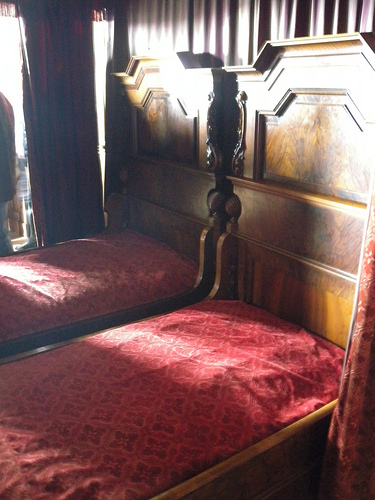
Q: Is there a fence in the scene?
A: No, there are no fences.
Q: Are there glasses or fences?
A: No, there are no fences or glasses.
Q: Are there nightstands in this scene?
A: No, there are no nightstands.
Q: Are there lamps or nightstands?
A: No, there are no nightstands or lamps.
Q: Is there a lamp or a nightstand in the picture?
A: No, there are no nightstands or lamps.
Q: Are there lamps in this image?
A: No, there are no lamps.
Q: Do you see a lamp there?
A: No, there are no lamps.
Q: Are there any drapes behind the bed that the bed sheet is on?
A: Yes, there are drapes behind the bed.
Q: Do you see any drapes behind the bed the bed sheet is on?
A: Yes, there are drapes behind the bed.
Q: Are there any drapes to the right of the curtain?
A: Yes, there are drapes to the right of the curtain.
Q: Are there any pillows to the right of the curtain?
A: No, there are drapes to the right of the curtain.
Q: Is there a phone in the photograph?
A: No, there are no phones.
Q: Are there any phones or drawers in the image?
A: No, there are no phones or drawers.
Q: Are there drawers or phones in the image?
A: No, there are no phones or drawers.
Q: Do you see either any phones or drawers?
A: No, there are no phones or drawers.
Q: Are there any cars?
A: No, there are no cars.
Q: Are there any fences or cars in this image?
A: No, there are no cars or fences.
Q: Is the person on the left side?
A: Yes, the person is on the left of the image.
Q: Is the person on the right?
A: No, the person is on the left of the image.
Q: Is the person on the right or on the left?
A: The person is on the left of the image.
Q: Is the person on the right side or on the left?
A: The person is on the left of the image.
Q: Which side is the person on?
A: The person is on the left of the image.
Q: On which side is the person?
A: The person is on the left of the image.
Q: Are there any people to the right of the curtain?
A: No, the person is to the left of the curtain.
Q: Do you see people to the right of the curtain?
A: No, the person is to the left of the curtain.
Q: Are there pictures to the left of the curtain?
A: No, there is a person to the left of the curtain.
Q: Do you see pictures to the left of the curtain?
A: No, there is a person to the left of the curtain.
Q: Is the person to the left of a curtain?
A: Yes, the person is to the left of a curtain.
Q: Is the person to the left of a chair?
A: No, the person is to the left of a curtain.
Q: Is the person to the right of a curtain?
A: No, the person is to the left of a curtain.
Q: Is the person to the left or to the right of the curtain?
A: The person is to the left of the curtain.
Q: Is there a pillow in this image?
A: No, there are no pillows.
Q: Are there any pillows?
A: No, there are no pillows.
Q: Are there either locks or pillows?
A: No, there are no pillows or locks.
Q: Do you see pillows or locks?
A: No, there are no pillows or locks.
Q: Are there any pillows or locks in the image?
A: No, there are no pillows or locks.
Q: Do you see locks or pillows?
A: No, there are no pillows or locks.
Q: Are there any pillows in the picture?
A: No, there are no pillows.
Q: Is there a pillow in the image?
A: No, there are no pillows.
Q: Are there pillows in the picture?
A: No, there are no pillows.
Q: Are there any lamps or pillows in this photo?
A: No, there are no pillows or lamps.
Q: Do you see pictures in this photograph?
A: No, there are no pictures.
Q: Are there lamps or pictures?
A: No, there are no pictures or lamps.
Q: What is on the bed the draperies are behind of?
A: The sheet is on the bed.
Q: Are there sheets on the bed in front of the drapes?
A: Yes, there is a sheet on the bed.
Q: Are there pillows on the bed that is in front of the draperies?
A: No, there is a sheet on the bed.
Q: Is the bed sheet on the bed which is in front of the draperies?
A: Yes, the sheet is on the bed.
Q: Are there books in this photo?
A: No, there are no books.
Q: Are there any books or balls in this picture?
A: No, there are no books or balls.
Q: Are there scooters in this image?
A: No, there are no scooters.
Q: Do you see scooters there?
A: No, there are no scooters.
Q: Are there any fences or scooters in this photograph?
A: No, there are no scooters or fences.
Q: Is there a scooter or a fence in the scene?
A: No, there are no scooters or fences.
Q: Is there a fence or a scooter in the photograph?
A: No, there are no scooters or fences.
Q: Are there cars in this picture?
A: No, there are no cars.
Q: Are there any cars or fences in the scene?
A: No, there are no cars or fences.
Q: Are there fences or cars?
A: No, there are no cars or fences.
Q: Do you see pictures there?
A: No, there are no pictures.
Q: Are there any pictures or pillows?
A: No, there are no pictures or pillows.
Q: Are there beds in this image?
A: Yes, there is a bed.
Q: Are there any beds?
A: Yes, there is a bed.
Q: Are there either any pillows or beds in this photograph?
A: Yes, there is a bed.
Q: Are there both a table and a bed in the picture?
A: No, there is a bed but no tables.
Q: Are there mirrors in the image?
A: No, there are no mirrors.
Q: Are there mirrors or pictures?
A: No, there are no mirrors or pictures.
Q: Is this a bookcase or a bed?
A: This is a bed.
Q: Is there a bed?
A: Yes, there is a bed.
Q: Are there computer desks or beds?
A: Yes, there is a bed.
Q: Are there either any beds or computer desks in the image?
A: Yes, there is a bed.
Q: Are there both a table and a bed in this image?
A: No, there is a bed but no tables.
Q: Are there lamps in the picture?
A: No, there are no lamps.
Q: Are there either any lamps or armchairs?
A: No, there are no lamps or armchairs.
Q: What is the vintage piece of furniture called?
A: The piece of furniture is a bed.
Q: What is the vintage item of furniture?
A: The piece of furniture is a bed.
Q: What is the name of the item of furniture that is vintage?
A: The piece of furniture is a bed.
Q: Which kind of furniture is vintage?
A: The furniture is a bed.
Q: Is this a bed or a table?
A: This is a bed.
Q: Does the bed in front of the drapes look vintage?
A: Yes, the bed is vintage.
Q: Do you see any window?
A: Yes, there is a window.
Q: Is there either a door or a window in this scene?
A: Yes, there is a window.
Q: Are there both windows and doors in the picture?
A: No, there is a window but no doors.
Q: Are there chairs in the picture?
A: No, there are no chairs.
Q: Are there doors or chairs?
A: No, there are no chairs or doors.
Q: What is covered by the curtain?
A: The window is covered by the curtain.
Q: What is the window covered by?
A: The window is covered by the curtain.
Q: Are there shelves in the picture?
A: No, there are no shelves.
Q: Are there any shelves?
A: No, there are no shelves.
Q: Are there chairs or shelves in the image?
A: No, there are no shelves or chairs.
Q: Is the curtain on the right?
A: No, the curtain is on the left of the image.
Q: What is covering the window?
A: The curtain is covering the window.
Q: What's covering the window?
A: The curtain is covering the window.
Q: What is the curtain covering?
A: The curtain is covering the window.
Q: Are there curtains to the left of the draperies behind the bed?
A: Yes, there is a curtain to the left of the draperies.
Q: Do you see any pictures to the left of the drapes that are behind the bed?
A: No, there is a curtain to the left of the drapes.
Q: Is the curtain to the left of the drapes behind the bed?
A: Yes, the curtain is to the left of the draperies.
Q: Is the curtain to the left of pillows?
A: No, the curtain is to the left of the draperies.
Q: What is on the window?
A: The curtain is on the window.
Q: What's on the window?
A: The curtain is on the window.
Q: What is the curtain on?
A: The curtain is on the window.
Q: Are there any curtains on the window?
A: Yes, there is a curtain on the window.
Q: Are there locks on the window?
A: No, there is a curtain on the window.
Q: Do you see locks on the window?
A: No, there is a curtain on the window.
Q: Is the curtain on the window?
A: Yes, the curtain is on the window.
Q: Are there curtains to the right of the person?
A: Yes, there is a curtain to the right of the person.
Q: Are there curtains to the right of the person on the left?
A: Yes, there is a curtain to the right of the person.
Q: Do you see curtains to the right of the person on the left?
A: Yes, there is a curtain to the right of the person.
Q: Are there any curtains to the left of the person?
A: No, the curtain is to the right of the person.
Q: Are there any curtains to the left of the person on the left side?
A: No, the curtain is to the right of the person.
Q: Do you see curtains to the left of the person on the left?
A: No, the curtain is to the right of the person.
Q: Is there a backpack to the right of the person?
A: No, there is a curtain to the right of the person.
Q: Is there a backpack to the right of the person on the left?
A: No, there is a curtain to the right of the person.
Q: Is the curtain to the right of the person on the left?
A: Yes, the curtain is to the right of the person.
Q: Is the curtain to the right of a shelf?
A: No, the curtain is to the right of the person.